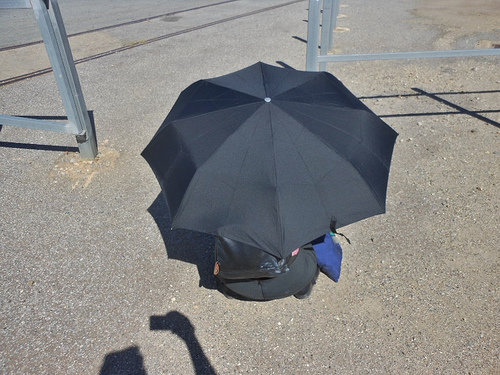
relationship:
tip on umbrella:
[239, 83, 292, 118] [189, 75, 329, 187]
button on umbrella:
[252, 80, 278, 116] [133, 55, 397, 255]